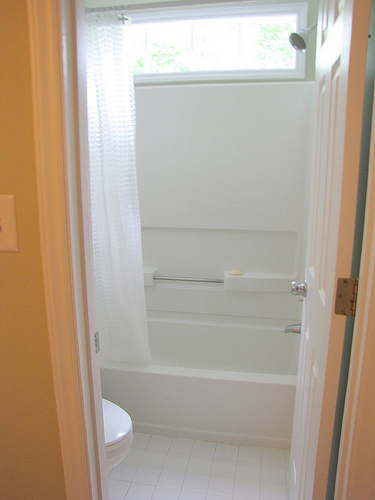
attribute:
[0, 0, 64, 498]
wall — painted, orange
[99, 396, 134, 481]
toilet — white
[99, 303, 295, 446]
tub — white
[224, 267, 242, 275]
soap — white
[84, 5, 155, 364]
curtain — clean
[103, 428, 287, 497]
floor — white, tile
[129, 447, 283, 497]
floor — white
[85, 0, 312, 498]
bathroom — white, open, clean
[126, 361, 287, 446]
tub wall — white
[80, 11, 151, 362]
shower curtain — white opaque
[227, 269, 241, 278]
soap — peach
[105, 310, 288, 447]
tub — white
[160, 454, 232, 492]
tiles — floor, white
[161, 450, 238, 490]
tiles — white, floor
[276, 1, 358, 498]
door — open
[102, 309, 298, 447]
bathtub — white, shallow, empty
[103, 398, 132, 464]
toilet — white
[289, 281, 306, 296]
knob — door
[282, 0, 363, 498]
door — brown, bathroom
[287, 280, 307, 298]
knob — door, metal